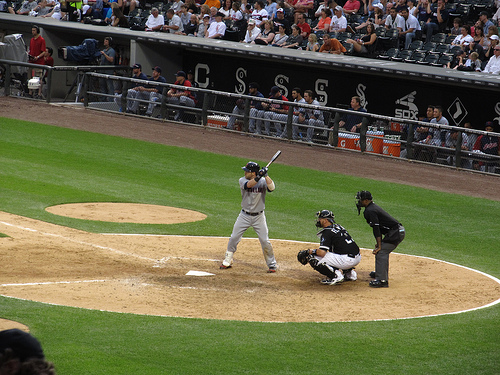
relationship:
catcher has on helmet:
[295, 207, 362, 287] [314, 208, 326, 228]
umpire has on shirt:
[355, 189, 407, 288] [362, 204, 402, 238]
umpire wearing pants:
[355, 183, 412, 286] [372, 232, 401, 279]